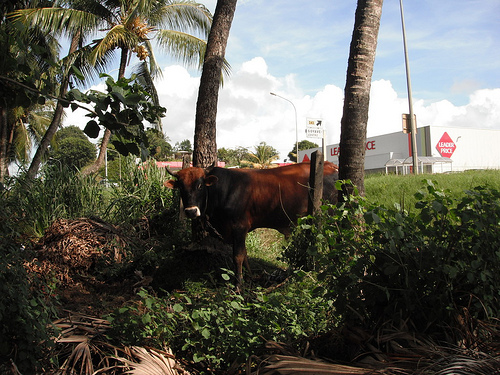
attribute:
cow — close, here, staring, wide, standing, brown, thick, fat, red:
[171, 163, 346, 247]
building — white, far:
[383, 115, 486, 169]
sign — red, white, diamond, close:
[432, 124, 465, 162]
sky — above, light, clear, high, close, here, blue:
[233, 20, 335, 116]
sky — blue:
[34, 2, 479, 112]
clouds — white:
[15, 43, 484, 173]